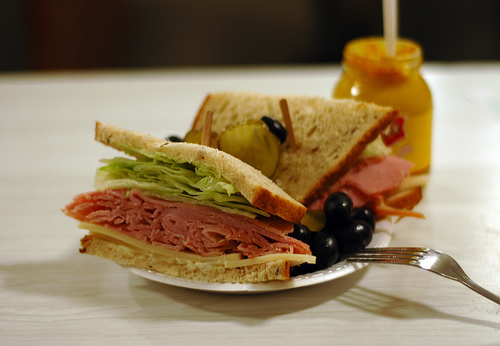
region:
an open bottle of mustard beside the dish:
[332, 3, 445, 184]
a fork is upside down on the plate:
[345, 236, 499, 305]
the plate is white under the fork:
[113, 217, 394, 290]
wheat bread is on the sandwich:
[73, 92, 397, 293]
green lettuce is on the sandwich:
[94, 148, 246, 217]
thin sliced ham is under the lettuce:
[58, 185, 313, 258]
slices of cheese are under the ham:
[73, 217, 315, 269]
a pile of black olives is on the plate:
[282, 190, 379, 277]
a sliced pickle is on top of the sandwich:
[214, 112, 286, 179]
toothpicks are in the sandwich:
[192, 94, 303, 184]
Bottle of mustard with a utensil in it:
[331, 33, 438, 200]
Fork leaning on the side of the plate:
[350, 238, 499, 308]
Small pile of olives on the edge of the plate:
[288, 191, 381, 269]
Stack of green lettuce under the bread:
[96, 145, 245, 215]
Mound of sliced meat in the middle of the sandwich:
[66, 186, 303, 265]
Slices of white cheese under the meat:
[75, 215, 315, 273]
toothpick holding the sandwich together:
[197, 107, 218, 149]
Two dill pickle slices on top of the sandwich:
[178, 118, 283, 178]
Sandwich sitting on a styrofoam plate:
[65, 88, 404, 295]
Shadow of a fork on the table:
[335, 275, 499, 337]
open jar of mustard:
[340, 30, 435, 194]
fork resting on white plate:
[348, 237, 491, 319]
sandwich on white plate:
[78, 85, 385, 278]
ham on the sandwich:
[67, 183, 297, 262]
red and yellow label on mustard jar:
[381, 120, 440, 172]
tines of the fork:
[354, 242, 421, 274]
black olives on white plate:
[295, 188, 372, 262]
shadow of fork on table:
[334, 272, 499, 334]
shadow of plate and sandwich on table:
[27, 235, 236, 321]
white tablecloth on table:
[2, 26, 484, 343]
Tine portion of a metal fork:
[348, 245, 498, 302]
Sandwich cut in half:
[58, 89, 426, 285]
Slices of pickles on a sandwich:
[185, 119, 282, 180]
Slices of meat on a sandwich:
[57, 185, 315, 258]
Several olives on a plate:
[287, 190, 376, 274]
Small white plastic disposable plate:
[123, 216, 395, 295]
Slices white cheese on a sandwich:
[75, 220, 317, 268]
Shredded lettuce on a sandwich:
[91, 143, 241, 205]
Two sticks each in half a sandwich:
[200, 98, 295, 148]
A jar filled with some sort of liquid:
[328, 38, 433, 200]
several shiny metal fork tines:
[348, 240, 428, 267]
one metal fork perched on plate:
[336, 241, 498, 316]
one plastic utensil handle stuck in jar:
[328, 2, 430, 94]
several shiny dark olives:
[308, 191, 378, 267]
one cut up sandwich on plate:
[58, 89, 404, 292]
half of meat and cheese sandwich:
[71, 115, 307, 287]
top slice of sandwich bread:
[95, 116, 313, 218]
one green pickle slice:
[216, 110, 293, 176]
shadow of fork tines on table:
[329, 274, 499, 340]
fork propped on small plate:
[339, 239, 499, 314]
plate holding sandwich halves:
[86, 166, 398, 290]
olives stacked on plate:
[279, 183, 374, 276]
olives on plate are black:
[272, 181, 382, 284]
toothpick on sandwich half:
[196, 105, 219, 148]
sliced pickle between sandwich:
[200, 109, 283, 184]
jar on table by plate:
[332, 36, 434, 208]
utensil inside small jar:
[379, 2, 400, 59]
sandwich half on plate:
[66, 112, 322, 292]